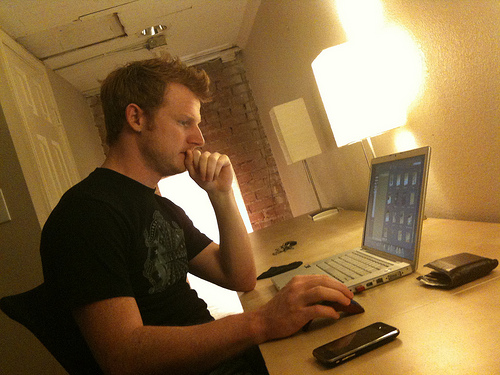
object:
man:
[37, 51, 351, 375]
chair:
[1, 278, 96, 375]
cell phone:
[311, 320, 403, 367]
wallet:
[412, 248, 499, 291]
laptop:
[268, 146, 434, 304]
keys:
[271, 241, 297, 256]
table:
[418, 299, 498, 375]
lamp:
[268, 98, 340, 221]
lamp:
[308, 37, 414, 159]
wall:
[174, 51, 295, 236]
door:
[1, 28, 85, 226]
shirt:
[40, 164, 214, 367]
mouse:
[291, 291, 367, 332]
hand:
[252, 267, 356, 339]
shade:
[299, 97, 327, 159]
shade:
[400, 39, 422, 110]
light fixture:
[137, 24, 171, 52]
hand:
[186, 147, 232, 190]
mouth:
[176, 149, 188, 158]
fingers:
[213, 155, 231, 180]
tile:
[6, 12, 131, 64]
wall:
[429, 2, 499, 222]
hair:
[102, 59, 150, 95]